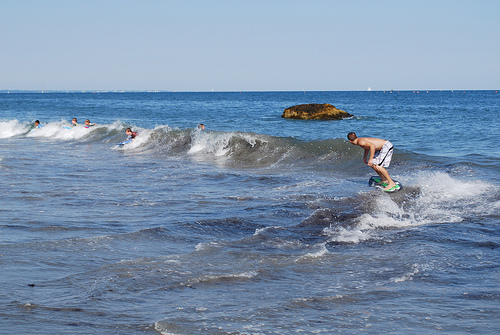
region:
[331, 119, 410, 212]
Man on a surfboard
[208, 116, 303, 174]
waves crashing in the ocean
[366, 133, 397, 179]
boy wearing plaid shorts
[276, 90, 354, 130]
rock in the ocean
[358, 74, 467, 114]
boats in the ocean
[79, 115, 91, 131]
people swimming in the water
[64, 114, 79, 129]
people swimming in the water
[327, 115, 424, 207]
man is on surfboard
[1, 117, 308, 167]
people are in wave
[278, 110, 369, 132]
brown rock in distance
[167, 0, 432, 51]
sky is blue and clear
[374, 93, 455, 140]
water is dark blue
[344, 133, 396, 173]
man has brown hair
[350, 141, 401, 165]
black and white shorts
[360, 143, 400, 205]
man on green board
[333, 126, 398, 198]
surfer riding a wave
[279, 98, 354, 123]
rock jutting out from the water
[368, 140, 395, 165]
board shorts worn by surfer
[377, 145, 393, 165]
black stripe on board shorts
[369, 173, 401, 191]
blue surfboard being ridden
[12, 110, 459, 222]
wave surfer is riding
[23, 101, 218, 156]
swimmers and surfers in the wave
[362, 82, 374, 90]
ship on the horizon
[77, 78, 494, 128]
ripples in the ocean waters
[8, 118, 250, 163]
white foam on the wave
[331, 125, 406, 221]
Man on a surf board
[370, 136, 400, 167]
man wearing plaid shorts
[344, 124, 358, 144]
man with brown hair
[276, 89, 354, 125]
rock in the middle of the ocean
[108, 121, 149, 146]
Man on a surf board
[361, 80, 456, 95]
Sailboats in the ocean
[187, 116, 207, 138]
person swimming in the ocean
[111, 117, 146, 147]
person swimming in the ocean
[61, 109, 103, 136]
person swimming in the ocean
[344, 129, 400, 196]
teenage boy on surf board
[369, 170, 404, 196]
black and green surf board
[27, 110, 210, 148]
group of people surfing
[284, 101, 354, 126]
small island in middle of sea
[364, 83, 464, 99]
group of sail boats in background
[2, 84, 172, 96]
cliff off coast in distance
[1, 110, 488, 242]
small wave in water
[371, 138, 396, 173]
black and white board shorts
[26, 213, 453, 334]
small waves in water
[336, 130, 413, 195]
man sufing a sufrboard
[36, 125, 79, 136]
white sea foam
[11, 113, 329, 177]
small waves on the sea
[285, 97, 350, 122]
stone in the middle of the ocean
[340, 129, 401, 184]
shirtless man surfing on board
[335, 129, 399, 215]
man whit gray short pants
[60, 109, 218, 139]
people surfing in the sea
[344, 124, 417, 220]
shirtless man surfing in the sea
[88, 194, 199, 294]
Large body of water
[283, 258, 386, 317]
Large body of water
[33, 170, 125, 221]
Large body of water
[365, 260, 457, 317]
Large body of water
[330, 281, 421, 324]
Large body of water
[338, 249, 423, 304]
Large body of water